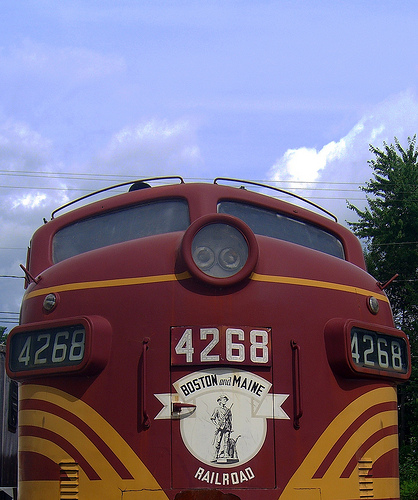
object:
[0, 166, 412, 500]
train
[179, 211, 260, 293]
headlight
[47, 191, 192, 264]
window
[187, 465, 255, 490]
word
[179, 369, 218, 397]
word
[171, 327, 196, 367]
numbers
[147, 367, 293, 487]
logo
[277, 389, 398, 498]
design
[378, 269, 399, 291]
handle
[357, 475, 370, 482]
vents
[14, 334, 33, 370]
number 4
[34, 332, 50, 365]
number 2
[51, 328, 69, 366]
number 6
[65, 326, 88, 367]
number 8